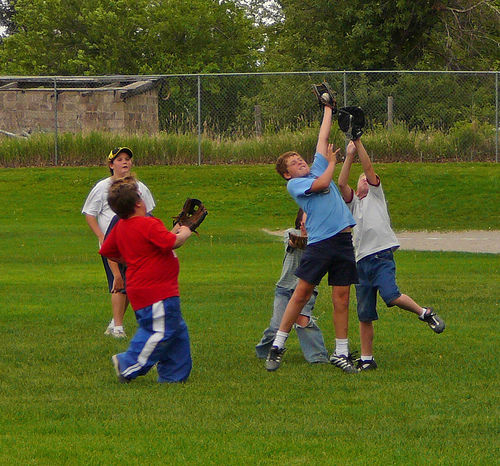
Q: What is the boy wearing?
A: A red shirt.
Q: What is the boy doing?
A: Catching the baseball.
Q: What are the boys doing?
A: Running to catch the ball.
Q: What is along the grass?
A: A fence.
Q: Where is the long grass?
A: Behind fence.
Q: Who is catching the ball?
A: A boy.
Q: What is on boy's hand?
A: Glove.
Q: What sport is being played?
A: Baseball.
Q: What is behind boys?
A: Fence.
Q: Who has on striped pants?
A: Boy in red shirt.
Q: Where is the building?
A: In background.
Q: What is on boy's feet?
A: Shoes.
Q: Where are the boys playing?
A: In the grass.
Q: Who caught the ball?
A: Boy in blue shirt.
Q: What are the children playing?
A: Baseball.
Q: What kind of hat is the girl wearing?
A: Baseball.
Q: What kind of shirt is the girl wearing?
A: T shirt.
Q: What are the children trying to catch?
A: Ball.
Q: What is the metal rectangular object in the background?
A: A fence.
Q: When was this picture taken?
A: Daytime.